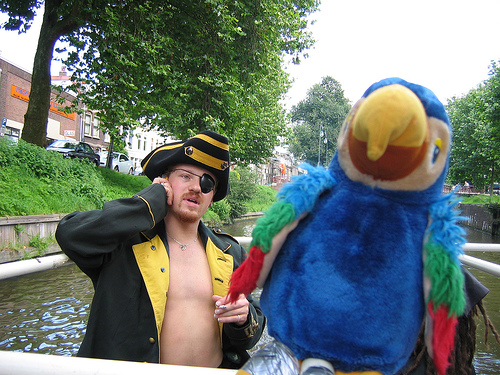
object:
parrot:
[225, 77, 490, 372]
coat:
[53, 180, 271, 369]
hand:
[152, 174, 172, 202]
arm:
[424, 229, 471, 315]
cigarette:
[209, 296, 232, 313]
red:
[228, 251, 265, 302]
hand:
[208, 289, 252, 329]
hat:
[140, 127, 236, 204]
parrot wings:
[217, 159, 332, 308]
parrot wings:
[419, 190, 472, 373]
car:
[42, 136, 103, 164]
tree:
[0, 0, 313, 160]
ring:
[164, 180, 170, 187]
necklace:
[163, 225, 205, 251]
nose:
[350, 82, 428, 160]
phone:
[154, 170, 168, 192]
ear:
[159, 173, 172, 191]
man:
[48, 130, 271, 370]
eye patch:
[197, 173, 219, 195]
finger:
[157, 179, 176, 207]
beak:
[348, 82, 433, 181]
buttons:
[182, 146, 198, 158]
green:
[253, 209, 283, 244]